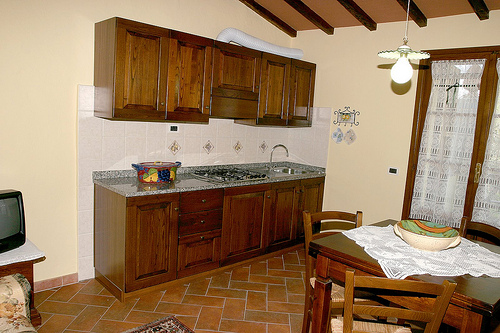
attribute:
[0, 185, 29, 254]
small tv — off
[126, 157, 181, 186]
pot — colorful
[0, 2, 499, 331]
pictures — kitchen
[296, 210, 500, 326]
table — wooden, square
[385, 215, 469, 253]
bowl — large, round, colorful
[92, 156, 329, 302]
cabinets — wood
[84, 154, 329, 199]
countertop — marble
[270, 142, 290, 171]
faucet — silver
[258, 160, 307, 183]
sink — kitchen sink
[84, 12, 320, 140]
cabinets — top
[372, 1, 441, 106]
fixture — hanging, light, overhead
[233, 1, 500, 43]
rafters — exposed, wooden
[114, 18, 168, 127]
door — wooden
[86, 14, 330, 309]
cabinet — brown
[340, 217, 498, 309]
cloth — white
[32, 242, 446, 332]
floor — brick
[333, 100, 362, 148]
items — decorative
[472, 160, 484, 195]
knob — plated, brass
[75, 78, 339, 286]
backsplash — tile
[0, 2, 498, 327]
kitchen — small, neat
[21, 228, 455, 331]
tile — red, brick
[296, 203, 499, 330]
chairs — wooden